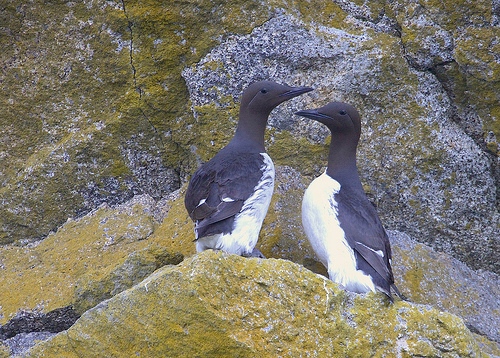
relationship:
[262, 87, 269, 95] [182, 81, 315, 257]
eyes on bird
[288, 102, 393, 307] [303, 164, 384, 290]
bird has white feathers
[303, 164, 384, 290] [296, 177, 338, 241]
white feathers are on chest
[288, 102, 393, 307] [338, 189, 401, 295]
bird has wings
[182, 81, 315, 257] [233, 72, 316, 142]
bird has black head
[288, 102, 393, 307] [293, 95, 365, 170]
bird has black head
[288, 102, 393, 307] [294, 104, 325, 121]
bird has beak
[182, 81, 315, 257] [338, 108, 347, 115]
bird has black eyes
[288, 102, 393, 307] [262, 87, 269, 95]
bird has eyes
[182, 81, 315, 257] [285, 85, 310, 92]
bird has beak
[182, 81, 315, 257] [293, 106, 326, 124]
bird has beak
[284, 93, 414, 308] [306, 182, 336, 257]
bird has chest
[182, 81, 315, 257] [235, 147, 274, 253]
bird has chest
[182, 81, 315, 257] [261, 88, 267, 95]
bird has eye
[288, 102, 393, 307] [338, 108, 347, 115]
bird has black eyes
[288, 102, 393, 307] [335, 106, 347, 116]
bird has eye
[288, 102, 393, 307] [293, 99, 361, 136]
bird has black head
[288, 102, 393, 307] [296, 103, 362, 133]
bird has head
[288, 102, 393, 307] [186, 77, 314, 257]
bird with bird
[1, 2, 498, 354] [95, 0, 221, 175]
rock with moss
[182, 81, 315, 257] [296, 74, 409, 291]
bird with bird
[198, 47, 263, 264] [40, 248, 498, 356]
bird sitting on rock